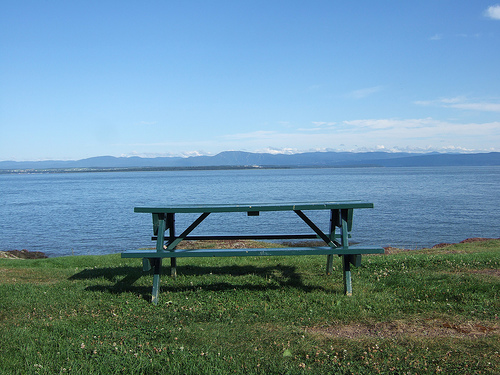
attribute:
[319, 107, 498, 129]
cloud — white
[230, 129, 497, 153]
cloud — white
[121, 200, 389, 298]
bench — empty, wooden, green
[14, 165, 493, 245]
water — calm, blue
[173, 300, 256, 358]
grass — green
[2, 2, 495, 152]
sky — clear, blue